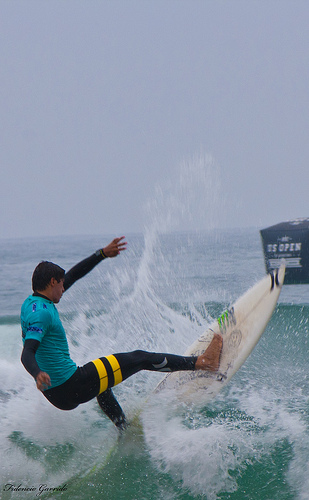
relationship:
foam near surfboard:
[4, 144, 308, 497] [86, 255, 289, 480]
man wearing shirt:
[20, 235, 224, 430] [20, 292, 79, 391]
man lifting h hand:
[20, 235, 224, 430] [105, 235, 127, 256]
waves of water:
[94, 283, 204, 355] [0, 223, 308, 497]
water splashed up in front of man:
[0, 144, 307, 366] [14, 235, 219, 428]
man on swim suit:
[20, 235, 224, 430] [20, 248, 198, 435]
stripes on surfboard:
[273, 266, 280, 286] [120, 260, 284, 463]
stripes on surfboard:
[268, 270, 274, 289] [120, 260, 284, 463]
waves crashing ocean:
[94, 283, 204, 355] [5, 231, 306, 498]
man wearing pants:
[20, 235, 224, 430] [39, 350, 203, 433]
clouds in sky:
[77, 89, 198, 190] [7, 33, 303, 231]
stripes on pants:
[87, 346, 126, 399] [39, 350, 203, 433]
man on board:
[14, 235, 219, 428] [128, 262, 286, 429]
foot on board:
[196, 329, 224, 372] [128, 262, 286, 429]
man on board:
[20, 235, 224, 430] [170, 257, 286, 388]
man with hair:
[14, 235, 219, 428] [28, 260, 68, 293]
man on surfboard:
[20, 235, 224, 430] [106, 267, 285, 455]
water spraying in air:
[0, 144, 307, 366] [3, 153, 299, 311]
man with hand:
[20, 235, 224, 430] [101, 233, 128, 257]